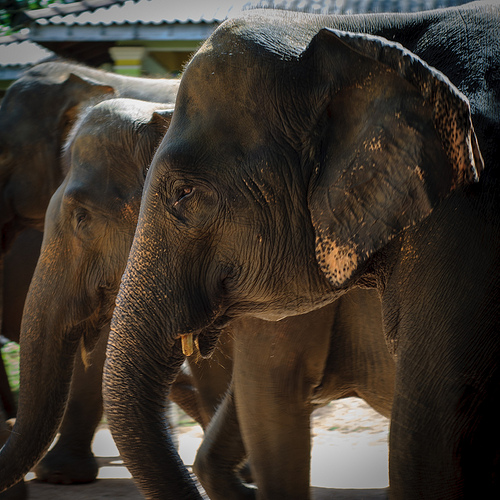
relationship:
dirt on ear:
[298, 44, 458, 271] [296, 25, 487, 290]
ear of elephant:
[296, 25, 487, 290] [179, 26, 445, 296]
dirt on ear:
[440, 86, 484, 183] [296, 25, 487, 290]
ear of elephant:
[296, 25, 487, 290] [103, 0, 498, 497]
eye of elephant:
[175, 181, 198, 200] [103, 0, 498, 497]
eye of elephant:
[59, 205, 97, 233] [14, 97, 396, 493]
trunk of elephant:
[1, 230, 79, 494] [1, 95, 178, 492]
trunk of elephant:
[96, 247, 205, 499] [103, 0, 498, 497]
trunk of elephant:
[99, 251, 208, 500] [103, 0, 498, 497]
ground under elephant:
[412, 158, 447, 219] [103, 0, 498, 497]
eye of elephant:
[173, 181, 199, 205] [103, 0, 498, 497]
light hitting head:
[236, 5, 303, 42] [154, 12, 397, 354]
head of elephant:
[154, 12, 397, 354] [103, 0, 498, 497]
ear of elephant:
[295, 25, 487, 290] [100, 26, 484, 481]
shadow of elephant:
[11, 456, 391, 498] [1, 95, 178, 492]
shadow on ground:
[11, 456, 391, 498] [5, 403, 407, 497]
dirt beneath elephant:
[310, 396, 389, 496] [103, 0, 498, 497]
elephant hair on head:
[63, 104, 93, 149] [157, 9, 397, 319]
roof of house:
[41, 7, 257, 50] [19, 4, 481, 93]